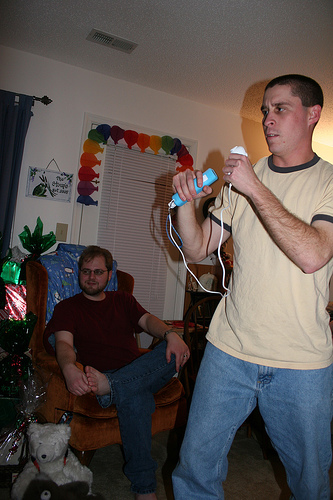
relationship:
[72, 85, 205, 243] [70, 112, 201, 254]
window has blinds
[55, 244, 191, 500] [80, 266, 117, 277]
man wears glasses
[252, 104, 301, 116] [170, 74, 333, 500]
eye of man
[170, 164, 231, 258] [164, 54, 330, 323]
hand of person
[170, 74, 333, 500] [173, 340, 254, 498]
man has leg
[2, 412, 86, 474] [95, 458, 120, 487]
bear sitting on floor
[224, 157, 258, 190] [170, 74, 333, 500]
hand of man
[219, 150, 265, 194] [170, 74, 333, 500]
hand of man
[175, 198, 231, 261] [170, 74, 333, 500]
arm of a man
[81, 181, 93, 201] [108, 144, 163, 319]
balloon over window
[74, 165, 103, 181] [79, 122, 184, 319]
balloon over window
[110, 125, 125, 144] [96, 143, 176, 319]
balloon over window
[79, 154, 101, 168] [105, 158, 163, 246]
balloon over window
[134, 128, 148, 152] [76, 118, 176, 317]
balloon over window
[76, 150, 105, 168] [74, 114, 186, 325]
paper balloon over window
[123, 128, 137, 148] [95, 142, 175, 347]
paper balloon over window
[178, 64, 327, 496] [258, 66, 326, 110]
man has hair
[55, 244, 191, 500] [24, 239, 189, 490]
man sitting on chair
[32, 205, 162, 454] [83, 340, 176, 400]
man has leg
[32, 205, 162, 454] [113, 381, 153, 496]
man has leg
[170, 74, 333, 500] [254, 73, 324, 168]
man has head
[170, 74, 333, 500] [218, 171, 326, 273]
man has arm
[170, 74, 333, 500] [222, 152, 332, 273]
man has arm